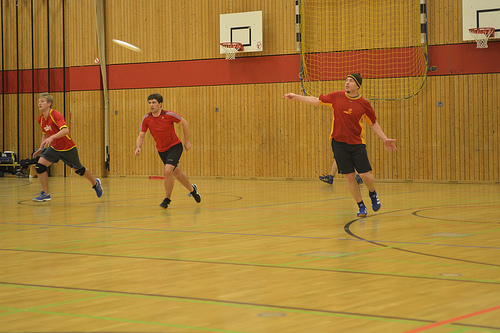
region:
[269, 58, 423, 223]
Man preparing to catch frisbee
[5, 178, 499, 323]
Basketball court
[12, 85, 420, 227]
Three sports players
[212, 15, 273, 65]
Basketball hoop and white backboard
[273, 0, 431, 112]
Net hanging on the wall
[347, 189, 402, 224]
Blue shoes on young man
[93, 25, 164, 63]
White frisbee flying through the air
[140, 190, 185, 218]
Black shoes being worn by player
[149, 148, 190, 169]
Black shorts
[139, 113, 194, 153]
Red Shirt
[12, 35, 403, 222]
Men playing with a frisbee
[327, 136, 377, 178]
Man is wearing shorts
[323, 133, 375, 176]
Man is wearing black shorts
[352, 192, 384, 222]
Man is wearing shoes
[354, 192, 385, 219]
Man is wearing blue and white shoes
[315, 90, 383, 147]
Man is wearing a shirt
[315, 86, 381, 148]
Man is wearing a red and yellow shirt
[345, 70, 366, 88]
Man is wearing a knit hat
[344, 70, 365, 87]
Man is wearing a black knit hat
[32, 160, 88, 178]
Man is wearing knee pads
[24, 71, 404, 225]
Young men playing a sport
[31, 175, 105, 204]
A pair of sneakers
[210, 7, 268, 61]
Basketball net on a board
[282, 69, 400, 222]
A man jumping up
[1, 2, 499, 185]
Brown wooden beams on the wall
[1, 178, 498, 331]
Lines on the court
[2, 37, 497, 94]
A red thick line on the wall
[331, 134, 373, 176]
A pair of black shorts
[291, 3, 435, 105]
A net on the wall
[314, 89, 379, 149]
A red and yellow shirt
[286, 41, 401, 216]
man wearing red shirt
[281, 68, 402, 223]
man wearing dark shorts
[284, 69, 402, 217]
man wearing black cap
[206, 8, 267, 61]
one basketball hoop with white backboard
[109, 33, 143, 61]
one white frisbeen midair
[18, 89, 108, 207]
man wearing black knee guards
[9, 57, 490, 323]
three men playing sports in a gym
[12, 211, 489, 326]
wooden gym floor with lines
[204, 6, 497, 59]
two white basketball hoops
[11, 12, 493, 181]
gym wall with broad orange stripe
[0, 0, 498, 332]
the interior of a gymnasium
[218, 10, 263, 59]
a basketball hoop & backboard on the left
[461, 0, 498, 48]
a basketball hoop & backboard on the right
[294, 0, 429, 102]
a large net on the wall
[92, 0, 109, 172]
a divider curtain in the wall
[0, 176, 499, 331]
the hardwood basketball court surface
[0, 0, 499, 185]
the wood paneled wall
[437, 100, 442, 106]
a metal object on the wall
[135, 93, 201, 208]
a man playing a sport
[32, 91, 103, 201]
a man playing a sport on the far left